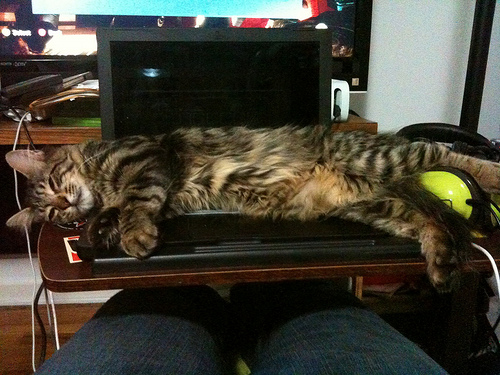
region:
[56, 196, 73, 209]
the cat's nose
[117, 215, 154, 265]
it is the paw of a cat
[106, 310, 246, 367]
blue jeans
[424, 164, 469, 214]
a pair of green headphones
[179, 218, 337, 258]
a black laptop computer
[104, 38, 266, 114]
the screen of the laptop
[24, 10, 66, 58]
a tv in the background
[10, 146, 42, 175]
the cat's ear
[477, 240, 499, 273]
a white cable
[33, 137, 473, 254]
cat laying on top of a laptop computer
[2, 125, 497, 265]
Cat laying on bench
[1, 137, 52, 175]
Left ear of cat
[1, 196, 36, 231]
Right ear of cat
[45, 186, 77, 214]
Nose of cat laying on bench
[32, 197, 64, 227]
Right eye of cat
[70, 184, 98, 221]
Mouth of cat laying on bench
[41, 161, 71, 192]
Left eye of cat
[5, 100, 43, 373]
White wire pluged into wall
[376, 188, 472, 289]
Back right leg of cat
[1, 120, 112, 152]
Front of tan shelf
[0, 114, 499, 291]
fuzzy striped furson, resting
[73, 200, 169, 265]
great big front paws on laptop, on shelf, over bedenimmed knees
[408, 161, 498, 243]
one side of chartreuse headphones betwixt pet legs+tail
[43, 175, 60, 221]
the half-opened eyes of a real fuzzbucket of a big happy cat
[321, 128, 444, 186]
a nearly tiger-striped knee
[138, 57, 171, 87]
the reflection of a lamplight in a laptop monitor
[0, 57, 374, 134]
a messy desk, beyond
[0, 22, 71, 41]
two illegible words beside circular logos in the distance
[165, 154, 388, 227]
fuzzy velutinous yellow underbelly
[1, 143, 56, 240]
the inside of certain pointy ears are pinkish brown+fur fluffed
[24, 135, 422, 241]
cat is sleeping on the keyboard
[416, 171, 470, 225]
there is a yellow mouse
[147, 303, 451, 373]
person is wearing jeans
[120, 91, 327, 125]
there is a moniter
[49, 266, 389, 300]
the table is made of wood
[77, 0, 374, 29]
there is a television in the back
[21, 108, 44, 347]
wires are hanging from phone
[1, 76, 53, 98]
there is a phone on the table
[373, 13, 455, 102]
the wall is white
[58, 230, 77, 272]
there is a red paper under the keyboard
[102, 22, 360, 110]
Black computer monitor.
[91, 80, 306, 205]
Computer is not turned on.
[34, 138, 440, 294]
Cat laying on computer.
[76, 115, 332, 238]
Cat is tiger striped.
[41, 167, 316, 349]
Computer sitting on brown desk.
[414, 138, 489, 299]
Computer mouse is yellow and black.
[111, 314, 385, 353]
Person wearing blue jeans.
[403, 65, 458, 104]
Wall is white in color.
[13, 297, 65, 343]
Hardwood floors on the ground.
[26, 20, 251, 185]
Person is sitting facing the television.